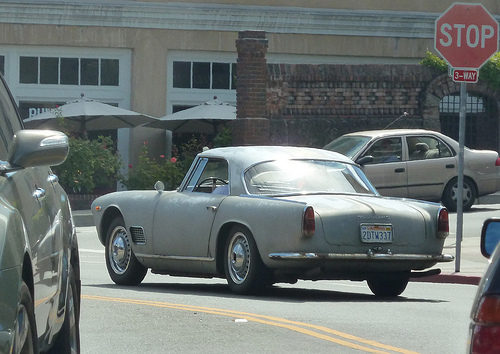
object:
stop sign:
[434, 3, 500, 70]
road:
[76, 203, 498, 353]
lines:
[79, 294, 417, 354]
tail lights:
[303, 206, 449, 239]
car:
[90, 145, 454, 297]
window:
[19, 56, 38, 84]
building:
[1, 0, 498, 211]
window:
[40, 57, 59, 84]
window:
[60, 57, 79, 85]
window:
[81, 58, 100, 85]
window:
[101, 59, 118, 86]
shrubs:
[50, 103, 231, 192]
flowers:
[128, 164, 133, 168]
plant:
[121, 141, 183, 190]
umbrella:
[142, 96, 236, 135]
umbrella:
[22, 93, 160, 132]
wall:
[235, 28, 498, 147]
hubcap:
[227, 232, 251, 284]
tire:
[224, 224, 269, 294]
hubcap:
[108, 226, 131, 275]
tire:
[105, 217, 149, 285]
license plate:
[361, 223, 392, 242]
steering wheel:
[197, 177, 229, 192]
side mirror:
[154, 181, 165, 193]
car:
[0, 73, 82, 353]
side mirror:
[2, 128, 70, 174]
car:
[322, 127, 499, 211]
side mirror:
[356, 155, 373, 163]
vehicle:
[467, 218, 498, 353]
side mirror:
[480, 218, 500, 259]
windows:
[173, 61, 237, 90]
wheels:
[53, 265, 80, 354]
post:
[455, 82, 465, 272]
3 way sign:
[453, 69, 479, 83]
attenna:
[383, 112, 410, 130]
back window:
[243, 159, 379, 195]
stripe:
[376, 182, 445, 189]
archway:
[420, 73, 499, 136]